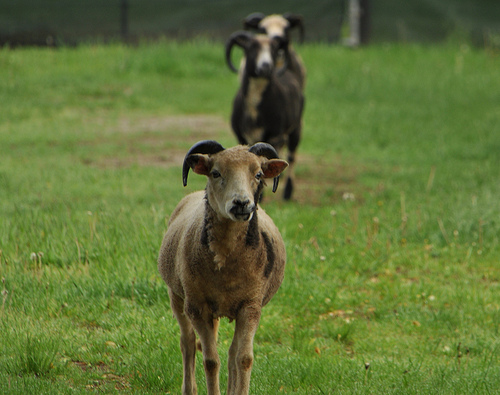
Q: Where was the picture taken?
A: It was taken at the field.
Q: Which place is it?
A: It is a field.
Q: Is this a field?
A: Yes, it is a field.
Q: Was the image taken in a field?
A: Yes, it was taken in a field.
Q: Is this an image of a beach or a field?
A: It is showing a field.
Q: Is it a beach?
A: No, it is a field.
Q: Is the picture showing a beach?
A: No, the picture is showing a field.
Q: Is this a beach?
A: No, it is a field.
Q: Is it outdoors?
A: Yes, it is outdoors.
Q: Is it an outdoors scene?
A: Yes, it is outdoors.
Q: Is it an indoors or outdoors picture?
A: It is outdoors.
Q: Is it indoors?
A: No, it is outdoors.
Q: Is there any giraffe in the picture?
A: No, there are no giraffes.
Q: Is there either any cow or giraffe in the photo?
A: No, there are no giraffes or cows.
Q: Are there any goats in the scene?
A: Yes, there is a goat.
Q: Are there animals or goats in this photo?
A: Yes, there is a goat.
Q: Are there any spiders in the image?
A: No, there are no spiders.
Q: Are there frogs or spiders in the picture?
A: No, there are no spiders or frogs.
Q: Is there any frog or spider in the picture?
A: No, there are no spiders or frogs.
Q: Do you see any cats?
A: No, there are no cats.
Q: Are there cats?
A: No, there are no cats.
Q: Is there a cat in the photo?
A: No, there are no cats.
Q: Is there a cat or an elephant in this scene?
A: No, there are no cats or elephants.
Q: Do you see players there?
A: No, there are no players.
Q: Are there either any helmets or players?
A: No, there are no players or helmets.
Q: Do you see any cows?
A: No, there are no cows.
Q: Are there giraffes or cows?
A: No, there are no cows or giraffes.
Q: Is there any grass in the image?
A: Yes, there is grass.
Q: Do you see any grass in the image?
A: Yes, there is grass.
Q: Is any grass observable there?
A: Yes, there is grass.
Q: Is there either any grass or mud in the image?
A: Yes, there is grass.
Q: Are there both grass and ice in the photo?
A: No, there is grass but no ice.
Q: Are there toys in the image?
A: No, there are no toys.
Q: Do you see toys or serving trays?
A: No, there are no toys or serving trays.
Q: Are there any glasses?
A: No, there are no glasses.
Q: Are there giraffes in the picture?
A: No, there are no giraffes.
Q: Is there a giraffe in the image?
A: No, there are no giraffes.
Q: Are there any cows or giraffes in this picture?
A: No, there are no giraffes or cows.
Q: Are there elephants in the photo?
A: No, there are no elephants.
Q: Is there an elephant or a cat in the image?
A: No, there are no elephants or cats.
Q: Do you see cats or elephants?
A: No, there are no elephants or cats.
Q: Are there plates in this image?
A: No, there are no plates.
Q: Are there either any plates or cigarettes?
A: No, there are no plates or cigarettes.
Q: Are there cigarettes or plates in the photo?
A: No, there are no plates or cigarettes.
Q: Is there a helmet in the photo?
A: No, there are no helmets.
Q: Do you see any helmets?
A: No, there are no helmets.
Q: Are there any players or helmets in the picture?
A: No, there are no helmets or players.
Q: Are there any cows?
A: No, there are no cows.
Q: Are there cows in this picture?
A: No, there are no cows.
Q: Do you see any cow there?
A: No, there are no cows.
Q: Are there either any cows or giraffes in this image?
A: No, there are no cows or giraffes.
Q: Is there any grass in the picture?
A: Yes, there is grass.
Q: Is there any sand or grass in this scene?
A: Yes, there is grass.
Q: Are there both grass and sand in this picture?
A: No, there is grass but no sand.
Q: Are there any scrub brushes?
A: No, there are no scrub brushes.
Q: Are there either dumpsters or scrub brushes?
A: No, there are no scrub brushes or dumpsters.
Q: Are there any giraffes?
A: No, there are no giraffes.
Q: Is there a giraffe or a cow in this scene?
A: No, there are no giraffes or cows.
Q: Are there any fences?
A: Yes, there is a fence.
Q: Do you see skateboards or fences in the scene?
A: Yes, there is a fence.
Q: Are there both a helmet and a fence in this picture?
A: No, there is a fence but no helmets.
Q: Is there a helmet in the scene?
A: No, there are no helmets.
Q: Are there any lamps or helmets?
A: No, there are no helmets or lamps.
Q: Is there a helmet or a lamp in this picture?
A: No, there are no helmets or lamps.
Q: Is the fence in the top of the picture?
A: Yes, the fence is in the top of the image.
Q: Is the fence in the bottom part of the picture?
A: No, the fence is in the top of the image.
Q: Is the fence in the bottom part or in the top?
A: The fence is in the top of the image.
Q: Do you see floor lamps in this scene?
A: No, there are no floor lamps.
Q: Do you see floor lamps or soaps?
A: No, there are no floor lamps or soaps.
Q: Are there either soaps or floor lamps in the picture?
A: No, there are no floor lamps or soaps.